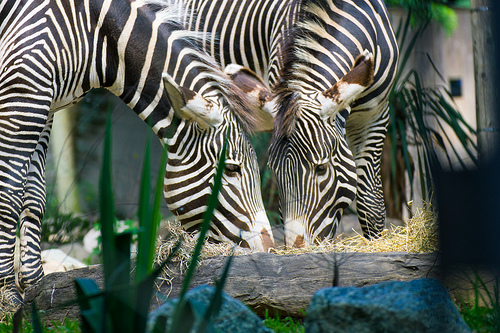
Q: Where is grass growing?
A: Front of rock.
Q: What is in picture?
A: Zebras.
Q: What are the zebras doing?
A: Eating.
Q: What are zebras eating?
A: Hay.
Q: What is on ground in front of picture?
A: Grass.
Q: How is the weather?
A: Sunny.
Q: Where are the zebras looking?
A: At the hay.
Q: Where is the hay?
A: On the ground.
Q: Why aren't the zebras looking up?
A: They are eating.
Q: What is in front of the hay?
A: Rocks.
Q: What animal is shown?
A: Zebra.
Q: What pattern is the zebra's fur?
A: Striped.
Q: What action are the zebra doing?
A: Eating.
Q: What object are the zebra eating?
A: Hay.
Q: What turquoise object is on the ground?
A: Rocks.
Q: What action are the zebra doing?
A: Grazing.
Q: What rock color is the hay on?
A: Gray.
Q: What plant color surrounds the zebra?
A: Dark green.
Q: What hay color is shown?
A: Yellow.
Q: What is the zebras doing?
A: Eating.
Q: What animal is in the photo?
A: Zebra.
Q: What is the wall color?
A: White.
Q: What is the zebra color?
A: Black and white.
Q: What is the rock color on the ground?
A: Blue.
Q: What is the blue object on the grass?
A: Rocks.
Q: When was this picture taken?
A: During the day.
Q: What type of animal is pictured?
A: A zebra.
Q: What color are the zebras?
A: Black and white.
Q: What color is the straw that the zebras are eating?
A: Yellow.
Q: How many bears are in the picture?
A: Zero.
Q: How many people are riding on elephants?
A: Zero.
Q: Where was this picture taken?
A: At a zoo.